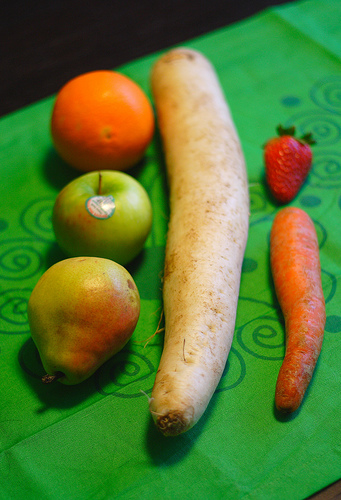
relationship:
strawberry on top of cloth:
[260, 122, 317, 201] [1, 2, 339, 499]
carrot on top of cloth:
[265, 206, 325, 417] [1, 2, 339, 499]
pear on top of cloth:
[26, 256, 140, 387] [1, 2, 339, 499]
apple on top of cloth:
[50, 168, 152, 268] [1, 2, 339, 499]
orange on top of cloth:
[50, 71, 154, 172] [1, 2, 339, 499]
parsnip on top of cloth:
[148, 47, 249, 437] [1, 2, 339, 499]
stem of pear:
[40, 366, 68, 387] [26, 256, 140, 387]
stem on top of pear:
[40, 366, 68, 387] [26, 256, 140, 387]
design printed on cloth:
[0, 73, 340, 399] [1, 2, 339, 499]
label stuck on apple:
[85, 192, 116, 221] [50, 168, 152, 268]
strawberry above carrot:
[260, 122, 317, 201] [265, 206, 325, 417]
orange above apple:
[50, 71, 154, 172] [50, 168, 152, 268]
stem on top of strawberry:
[260, 120, 316, 145] [260, 122, 317, 201]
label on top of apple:
[85, 192, 116, 221] [50, 168, 152, 268]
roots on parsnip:
[144, 391, 197, 441] [148, 47, 249, 437]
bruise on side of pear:
[124, 276, 140, 309] [26, 256, 140, 387]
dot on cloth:
[280, 94, 303, 109] [1, 2, 339, 499]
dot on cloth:
[298, 189, 323, 210] [1, 2, 339, 499]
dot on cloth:
[322, 310, 340, 340] [1, 2, 339, 499]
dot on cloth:
[239, 253, 261, 277] [1, 2, 339, 499]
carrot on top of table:
[268, 206, 325, 417] [1, 0, 340, 500]